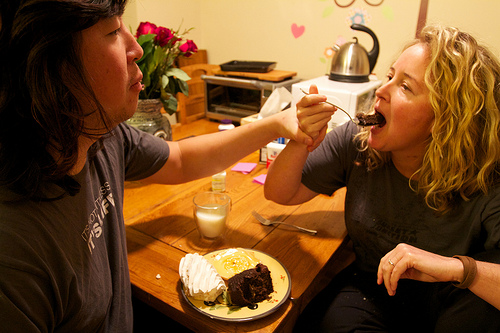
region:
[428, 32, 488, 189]
a curly blond head of hair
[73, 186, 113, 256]
writing on a shirt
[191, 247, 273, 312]
a delicious plate of food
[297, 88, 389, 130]
a fork full of food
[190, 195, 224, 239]
a glass of milk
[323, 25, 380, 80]
a silver kettle of water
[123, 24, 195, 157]
a vase full of red roses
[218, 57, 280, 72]
a cookie tray in the back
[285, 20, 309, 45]
a red paper heart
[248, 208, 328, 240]
a silver fork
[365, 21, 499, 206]
Head of woman eating food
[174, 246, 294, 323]
Plate of delicious snacks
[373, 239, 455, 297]
Hand of woman eating snack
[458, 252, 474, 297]
Wristwarch on woman's hand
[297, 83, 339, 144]
Hand of woman eating snack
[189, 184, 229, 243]
Glass of cold milk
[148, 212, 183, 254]
Part of wooden table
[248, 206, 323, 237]
Eating utensil resting on table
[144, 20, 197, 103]
Part of floral bouquet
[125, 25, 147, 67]
Nose of person watching woman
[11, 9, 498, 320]
a couple sit on a table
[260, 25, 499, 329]
the woman is blonde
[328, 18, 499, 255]
long hair of woman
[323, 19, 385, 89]
a kettle color silver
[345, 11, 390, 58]
handle of kettle is black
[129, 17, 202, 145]
red roses on a vase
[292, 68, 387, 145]
a hand holding a spoon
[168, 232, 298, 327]
a dish with pastries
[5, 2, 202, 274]
man has long hair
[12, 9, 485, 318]
two people sitting at a wood table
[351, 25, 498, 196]
woman with wavy blonde hair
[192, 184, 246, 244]
glass of milk on the table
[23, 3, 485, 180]
person holding woman's wrist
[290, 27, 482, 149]
woman eating a piece of chocolate cake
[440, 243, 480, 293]
brown bracelets on womans wrist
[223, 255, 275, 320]
chocolate cake on a plate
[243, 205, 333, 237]
silver fork on the table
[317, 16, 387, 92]
silver and black tea pot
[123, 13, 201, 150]
vase with red roses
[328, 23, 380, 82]
silver tea pot with black handle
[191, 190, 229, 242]
clear glass of milk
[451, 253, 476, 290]
two brown wrist bands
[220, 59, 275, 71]
small black tray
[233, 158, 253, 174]
pink Post It note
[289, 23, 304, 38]
pink heart on the wall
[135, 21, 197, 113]
bouquet of red roses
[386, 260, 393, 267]
silver colored wedding ring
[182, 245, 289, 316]
yellow glass plate with desserts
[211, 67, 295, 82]
brown wooden cutting board